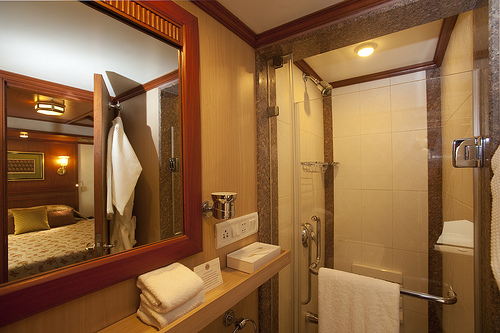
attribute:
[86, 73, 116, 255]
door — open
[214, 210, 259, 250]
white panel — long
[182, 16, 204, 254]
frame — wooden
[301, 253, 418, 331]
towel — white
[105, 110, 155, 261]
robe — white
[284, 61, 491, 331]
door — glass, hinged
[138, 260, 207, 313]
towel — white, folded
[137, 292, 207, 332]
towel — white, folded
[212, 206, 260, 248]
outlet — white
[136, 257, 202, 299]
white towels — folded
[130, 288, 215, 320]
white towels — folded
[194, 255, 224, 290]
sign — small